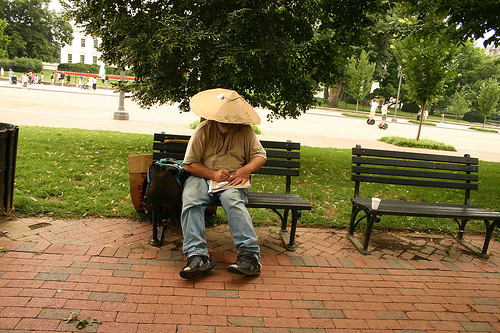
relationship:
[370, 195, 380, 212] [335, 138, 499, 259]
cup on bench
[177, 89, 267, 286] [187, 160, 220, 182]
man has arm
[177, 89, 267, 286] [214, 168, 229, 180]
man has hand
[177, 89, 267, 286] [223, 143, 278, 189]
man has hand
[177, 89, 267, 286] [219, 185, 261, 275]
man has leg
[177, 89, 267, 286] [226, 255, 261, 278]
man has foot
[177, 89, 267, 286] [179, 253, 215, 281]
man has foot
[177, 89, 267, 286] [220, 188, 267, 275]
man has leg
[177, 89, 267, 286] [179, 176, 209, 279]
man has leg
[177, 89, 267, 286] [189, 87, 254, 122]
man wearing hat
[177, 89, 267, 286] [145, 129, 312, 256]
man sitting on bench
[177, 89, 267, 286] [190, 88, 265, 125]
man wearing a hat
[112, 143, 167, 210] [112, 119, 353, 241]
bag on end of a bench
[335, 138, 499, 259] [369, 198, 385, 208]
bench has a coffee cup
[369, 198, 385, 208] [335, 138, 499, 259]
coffee cup sitting on a bench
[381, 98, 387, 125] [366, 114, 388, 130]
people riding segways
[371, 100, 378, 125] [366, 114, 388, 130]
people riding segways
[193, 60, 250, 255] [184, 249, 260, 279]
man wearing black sandals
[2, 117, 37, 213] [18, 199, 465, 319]
trash can next to a pathway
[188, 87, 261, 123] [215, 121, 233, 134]
hat on mans head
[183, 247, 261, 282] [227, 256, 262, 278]
shoes are on feet